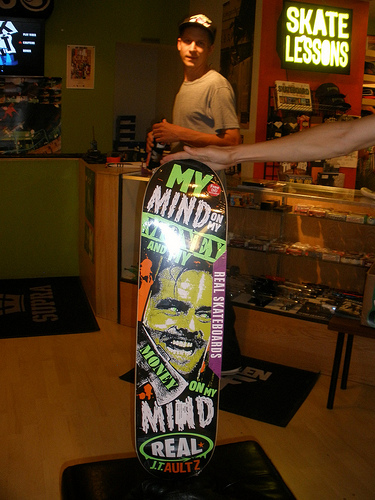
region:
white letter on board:
[145, 183, 170, 215]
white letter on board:
[174, 193, 193, 229]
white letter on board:
[141, 400, 164, 435]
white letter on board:
[165, 402, 175, 434]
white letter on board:
[150, 441, 165, 458]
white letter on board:
[163, 437, 176, 457]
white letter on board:
[164, 399, 173, 431]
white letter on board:
[173, 398, 194, 430]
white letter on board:
[195, 395, 214, 426]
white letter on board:
[175, 436, 190, 456]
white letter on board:
[188, 436, 201, 456]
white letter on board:
[193, 198, 210, 228]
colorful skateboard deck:
[136, 155, 230, 483]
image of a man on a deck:
[143, 255, 213, 387]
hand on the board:
[157, 143, 230, 177]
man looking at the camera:
[143, 12, 238, 379]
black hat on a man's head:
[178, 11, 217, 38]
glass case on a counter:
[113, 165, 373, 331]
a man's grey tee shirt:
[168, 71, 239, 203]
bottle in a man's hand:
[139, 124, 170, 172]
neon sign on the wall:
[276, 3, 353, 75]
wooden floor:
[3, 283, 373, 498]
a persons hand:
[200, 146, 224, 164]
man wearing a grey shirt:
[177, 88, 216, 127]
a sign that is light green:
[284, 9, 348, 67]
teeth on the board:
[167, 337, 196, 352]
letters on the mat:
[20, 283, 62, 324]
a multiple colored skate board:
[135, 157, 225, 473]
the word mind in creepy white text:
[143, 398, 212, 432]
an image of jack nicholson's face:
[143, 255, 213, 371]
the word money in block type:
[139, 343, 179, 390]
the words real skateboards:
[210, 268, 226, 361]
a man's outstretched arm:
[160, 119, 374, 173]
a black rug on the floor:
[119, 340, 320, 426]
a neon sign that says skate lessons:
[282, 2, 351, 65]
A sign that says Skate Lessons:
[280, 2, 352, 73]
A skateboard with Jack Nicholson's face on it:
[135, 158, 224, 481]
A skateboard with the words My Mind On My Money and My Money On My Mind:
[135, 157, 225, 477]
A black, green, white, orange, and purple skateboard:
[135, 159, 227, 480]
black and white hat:
[173, 10, 213, 42]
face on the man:
[168, 23, 205, 63]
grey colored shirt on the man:
[167, 66, 238, 156]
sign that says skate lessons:
[276, 7, 354, 61]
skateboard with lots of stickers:
[120, 146, 225, 476]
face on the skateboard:
[140, 263, 205, 378]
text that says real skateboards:
[210, 261, 222, 362]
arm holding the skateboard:
[153, 105, 369, 169]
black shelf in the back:
[109, 110, 136, 163]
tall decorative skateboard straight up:
[131, 155, 227, 479]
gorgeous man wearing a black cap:
[143, 13, 239, 376]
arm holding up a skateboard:
[132, 112, 374, 480]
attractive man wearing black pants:
[142, 13, 241, 375]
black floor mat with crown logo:
[0, 273, 101, 340]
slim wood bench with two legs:
[323, 313, 373, 409]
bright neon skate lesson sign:
[276, 0, 352, 76]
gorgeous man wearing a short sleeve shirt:
[140, 11, 240, 376]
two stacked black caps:
[314, 78, 352, 110]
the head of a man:
[171, 4, 216, 85]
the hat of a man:
[176, 3, 224, 35]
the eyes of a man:
[170, 32, 218, 51]